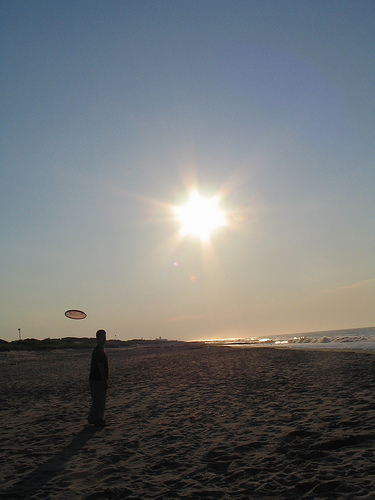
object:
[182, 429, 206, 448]
sand part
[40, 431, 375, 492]
ground part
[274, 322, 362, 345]
sea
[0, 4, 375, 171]
sky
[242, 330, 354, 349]
waves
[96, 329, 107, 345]
head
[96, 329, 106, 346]
face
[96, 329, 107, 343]
hair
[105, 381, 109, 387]
hand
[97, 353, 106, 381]
arm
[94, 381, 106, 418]
leg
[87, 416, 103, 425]
feet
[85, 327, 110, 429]
man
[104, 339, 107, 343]
chin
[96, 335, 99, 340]
ear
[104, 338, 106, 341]
nose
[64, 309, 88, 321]
frisbee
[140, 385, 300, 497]
beach sand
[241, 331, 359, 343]
sea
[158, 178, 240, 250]
sun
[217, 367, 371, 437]
sand